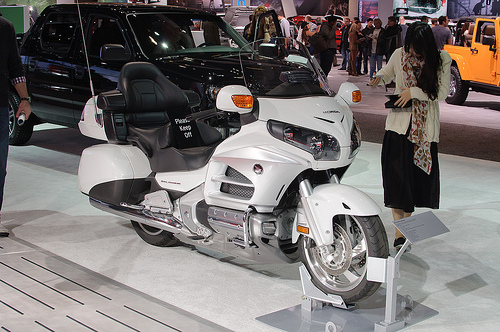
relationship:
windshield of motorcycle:
[238, 36, 334, 96] [78, 36, 388, 304]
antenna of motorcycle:
[76, 0, 96, 97] [78, 36, 388, 304]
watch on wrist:
[21, 96, 31, 101] [15, 95, 32, 125]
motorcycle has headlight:
[78, 36, 388, 304] [267, 117, 360, 161]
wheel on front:
[298, 183, 388, 303] [204, 36, 391, 304]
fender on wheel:
[291, 183, 381, 246] [298, 183, 388, 303]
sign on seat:
[166, 106, 206, 153] [116, 61, 223, 172]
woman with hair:
[367, 21, 452, 252] [404, 21, 442, 101]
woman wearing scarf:
[367, 21, 452, 252] [402, 46, 432, 175]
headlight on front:
[267, 117, 360, 161] [204, 36, 391, 304]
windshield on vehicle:
[238, 36, 334, 96] [78, 36, 388, 304]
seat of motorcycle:
[116, 61, 223, 172] [78, 36, 388, 304]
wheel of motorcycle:
[298, 183, 388, 303] [78, 36, 388, 304]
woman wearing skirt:
[367, 21, 452, 252] [380, 113, 440, 213]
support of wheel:
[299, 241, 411, 332] [298, 183, 388, 303]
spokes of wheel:
[304, 214, 366, 291] [298, 183, 388, 303]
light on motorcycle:
[231, 94, 254, 110] [78, 36, 388, 304]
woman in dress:
[367, 21, 452, 252] [382, 47, 452, 210]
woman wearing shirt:
[367, 21, 452, 252] [372, 46, 452, 142]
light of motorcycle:
[231, 94, 254, 110] [78, 36, 388, 304]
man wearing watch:
[0, 16, 31, 222] [21, 96, 31, 101]